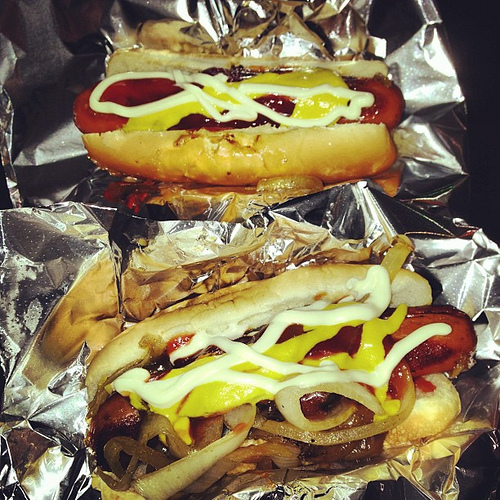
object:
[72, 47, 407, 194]
bun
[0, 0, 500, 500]
foil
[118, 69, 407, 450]
mustard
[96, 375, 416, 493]
onion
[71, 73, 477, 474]
hot dogs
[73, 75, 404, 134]
hot dog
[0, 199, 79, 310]
wave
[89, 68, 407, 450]
ketchup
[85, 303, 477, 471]
hot dog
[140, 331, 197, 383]
ketchup spot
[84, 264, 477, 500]
bun